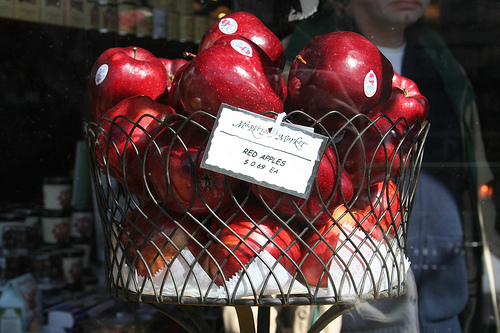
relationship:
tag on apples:
[199, 101, 329, 201] [90, 11, 427, 286]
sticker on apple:
[362, 69, 378, 98] [285, 29, 395, 117]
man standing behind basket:
[270, 0, 482, 332] [80, 112, 430, 306]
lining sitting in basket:
[104, 222, 410, 300] [80, 112, 430, 306]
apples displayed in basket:
[90, 11, 427, 286] [80, 112, 430, 306]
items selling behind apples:
[0, 177, 95, 284] [90, 11, 427, 286]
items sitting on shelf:
[0, 0, 219, 45] [0, 17, 202, 61]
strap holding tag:
[270, 111, 286, 135] [199, 101, 329, 201]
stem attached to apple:
[294, 54, 313, 71] [285, 29, 395, 117]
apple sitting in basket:
[285, 29, 395, 117] [80, 112, 430, 306]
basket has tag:
[80, 112, 430, 306] [199, 101, 329, 201]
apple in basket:
[285, 29, 395, 117] [80, 112, 430, 306]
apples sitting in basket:
[90, 11, 427, 286] [80, 112, 430, 306]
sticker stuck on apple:
[362, 69, 378, 98] [285, 29, 395, 117]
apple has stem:
[285, 29, 395, 117] [294, 54, 313, 71]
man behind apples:
[270, 0, 482, 332] [90, 11, 427, 286]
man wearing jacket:
[270, 0, 482, 332] [282, 18, 470, 315]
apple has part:
[285, 29, 395, 117] [323, 44, 359, 59]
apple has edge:
[285, 29, 395, 117] [317, 28, 365, 39]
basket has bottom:
[80, 112, 430, 306] [111, 289, 402, 306]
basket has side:
[80, 112, 430, 306] [76, 121, 120, 298]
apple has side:
[285, 29, 395, 117] [387, 60, 394, 106]